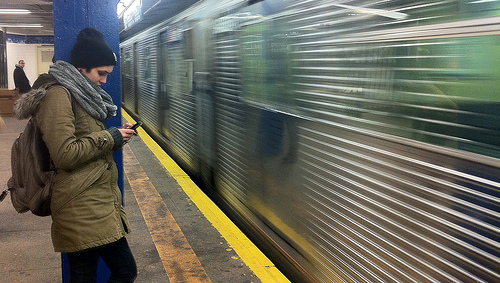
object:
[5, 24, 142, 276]
person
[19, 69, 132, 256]
jacket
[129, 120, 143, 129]
phone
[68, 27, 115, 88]
head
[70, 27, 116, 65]
hat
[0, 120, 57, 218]
backpack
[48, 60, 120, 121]
scarf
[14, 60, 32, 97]
man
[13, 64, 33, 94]
jacket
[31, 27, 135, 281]
beam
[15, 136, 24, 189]
zipper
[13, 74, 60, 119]
hood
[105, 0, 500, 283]
train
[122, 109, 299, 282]
line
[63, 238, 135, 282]
pants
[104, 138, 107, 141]
button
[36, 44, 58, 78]
door